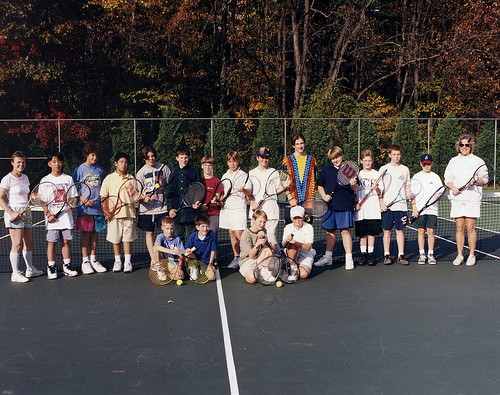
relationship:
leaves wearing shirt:
[7, 49, 51, 81] [450, 156, 482, 191]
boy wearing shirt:
[153, 214, 186, 284] [316, 163, 358, 213]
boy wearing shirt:
[180, 216, 217, 281] [165, 167, 202, 222]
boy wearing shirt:
[318, 144, 360, 270] [194, 176, 224, 213]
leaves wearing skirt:
[7, 49, 51, 81] [444, 192, 481, 218]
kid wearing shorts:
[39, 151, 97, 258] [69, 209, 103, 235]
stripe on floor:
[215, 263, 240, 393] [0, 264, 498, 391]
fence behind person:
[1, 114, 496, 204] [352, 147, 385, 267]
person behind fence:
[377, 143, 414, 268] [1, 114, 496, 204]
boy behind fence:
[410, 154, 443, 265] [1, 114, 496, 204]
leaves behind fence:
[7, 49, 51, 81] [1, 114, 496, 204]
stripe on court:
[215, 263, 240, 393] [4, 197, 499, 391]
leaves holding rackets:
[7, 49, 51, 81] [182, 178, 311, 215]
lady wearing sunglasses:
[444, 131, 489, 268] [455, 141, 474, 149]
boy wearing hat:
[410, 154, 443, 265] [419, 152, 432, 163]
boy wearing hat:
[244, 142, 288, 253] [257, 146, 269, 156]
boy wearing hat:
[280, 205, 315, 279] [290, 205, 304, 217]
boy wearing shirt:
[412, 152, 454, 267] [413, 168, 443, 212]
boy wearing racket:
[410, 154, 443, 265] [410, 184, 495, 218]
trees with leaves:
[2, 3, 498, 189] [447, 50, 492, 92]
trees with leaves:
[2, 3, 498, 189] [159, 4, 204, 40]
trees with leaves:
[2, 3, 498, 189] [7, 49, 70, 89]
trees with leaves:
[2, 3, 498, 189] [471, 7, 493, 30]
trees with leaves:
[2, 3, 498, 189] [124, 86, 175, 107]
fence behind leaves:
[1, 114, 496, 204] [7, 49, 51, 81]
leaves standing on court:
[7, 49, 51, 81] [4, 197, 499, 391]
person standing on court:
[354, 145, 380, 268] [4, 197, 499, 391]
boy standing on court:
[410, 154, 443, 265] [4, 197, 499, 391]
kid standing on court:
[38, 153, 79, 281] [4, 197, 499, 391]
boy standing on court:
[100, 155, 141, 272] [4, 197, 499, 391]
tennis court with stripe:
[0, 191, 498, 392] [215, 263, 240, 393]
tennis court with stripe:
[0, 191, 498, 392] [403, 225, 498, 262]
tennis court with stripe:
[0, 191, 498, 392] [438, 215, 499, 235]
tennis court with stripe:
[0, 191, 498, 392] [0, 216, 47, 242]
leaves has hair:
[7, 49, 51, 81] [455, 129, 475, 141]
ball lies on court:
[273, 280, 283, 288] [4, 197, 499, 391]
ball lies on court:
[172, 278, 184, 285] [4, 197, 499, 391]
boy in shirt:
[193, 155, 224, 270] [200, 175, 225, 217]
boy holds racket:
[193, 155, 224, 270] [208, 177, 230, 207]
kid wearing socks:
[0, 150, 43, 283] [8, 248, 34, 269]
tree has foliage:
[8, 100, 84, 138] [8, 105, 91, 153]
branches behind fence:
[328, 17, 479, 108] [0, 119, 499, 195]